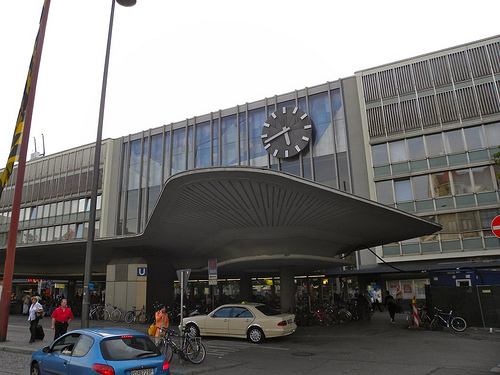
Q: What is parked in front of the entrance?
A: White car.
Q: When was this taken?
A: 5:43.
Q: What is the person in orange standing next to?
A: Bicycles.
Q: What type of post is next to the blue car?
A: Street lamp.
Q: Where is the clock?
A: Front of building.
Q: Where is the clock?
A: On the building.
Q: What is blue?
A: Car.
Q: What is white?
A: Sky.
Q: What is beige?
A: Car.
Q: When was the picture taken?
A: Daytime.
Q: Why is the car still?
A: Parked.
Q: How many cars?
A: Two.